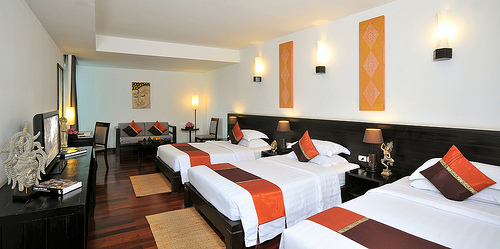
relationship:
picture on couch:
[131, 80, 152, 110] [116, 117, 176, 151]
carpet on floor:
[128, 172, 173, 199] [90, 149, 280, 245]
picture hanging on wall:
[131, 80, 152, 110] [98, 61, 192, 125]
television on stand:
[22, 94, 87, 174] [60, 155, 90, 185]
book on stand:
[22, 153, 120, 236] [38, 163, 98, 222]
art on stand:
[0, 123, 72, 190] [18, 184, 84, 230]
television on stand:
[31, 109, 69, 174] [42, 146, 84, 175]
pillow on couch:
[123, 118, 141, 136] [116, 118, 176, 167]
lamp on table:
[360, 124, 387, 178] [343, 167, 396, 196]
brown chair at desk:
[89, 120, 110, 161] [40, 123, 114, 184]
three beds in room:
[157, 120, 472, 244] [64, 35, 446, 239]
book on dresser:
[30, 174, 97, 203] [24, 138, 95, 231]